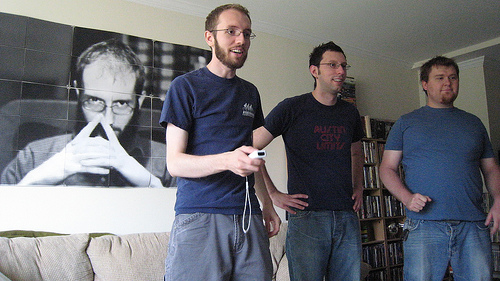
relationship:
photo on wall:
[2, 13, 217, 199] [1, 3, 430, 252]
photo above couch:
[2, 13, 217, 199] [0, 217, 297, 277]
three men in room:
[176, 3, 495, 265] [3, 3, 492, 276]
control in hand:
[238, 146, 268, 175] [235, 141, 260, 181]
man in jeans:
[158, 0, 285, 281] [392, 207, 488, 278]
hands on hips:
[274, 187, 368, 220] [272, 188, 362, 217]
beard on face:
[209, 39, 253, 69] [209, 6, 256, 65]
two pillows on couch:
[0, 232, 171, 279] [0, 229, 301, 279]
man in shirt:
[158, 0, 285, 281] [383, 103, 493, 226]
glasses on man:
[200, 22, 263, 44] [158, 0, 285, 281]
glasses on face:
[200, 22, 263, 44] [206, 3, 256, 68]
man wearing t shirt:
[158, 0, 285, 281] [159, 61, 270, 218]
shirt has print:
[167, 68, 274, 223] [239, 99, 260, 129]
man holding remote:
[158, 0, 285, 281] [248, 143, 264, 165]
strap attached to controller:
[238, 176, 257, 235] [247, 149, 268, 158]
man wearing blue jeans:
[158, 0, 285, 281] [164, 208, 279, 281]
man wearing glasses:
[158, 0, 285, 281] [204, 18, 257, 44]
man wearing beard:
[158, 0, 285, 281] [210, 31, 250, 72]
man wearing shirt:
[158, 0, 285, 281] [158, 64, 269, 218]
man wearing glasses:
[158, 0, 285, 281] [206, 22, 254, 41]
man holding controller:
[158, 0, 285, 281] [247, 149, 268, 158]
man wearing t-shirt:
[158, 0, 285, 281] [164, 66, 261, 218]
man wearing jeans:
[158, 0, 285, 281] [286, 202, 364, 276]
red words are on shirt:
[308, 122, 348, 157] [259, 86, 369, 213]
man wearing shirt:
[158, 0, 285, 281] [383, 103, 493, 226]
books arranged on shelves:
[359, 115, 408, 276] [348, 111, 405, 277]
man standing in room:
[374, 49, 498, 277] [3, 3, 492, 276]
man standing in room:
[246, 37, 381, 277] [3, 3, 492, 276]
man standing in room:
[158, 0, 271, 279] [3, 3, 492, 276]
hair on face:
[203, 4, 256, 26] [209, 6, 258, 70]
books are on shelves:
[359, 115, 408, 276] [351, 114, 410, 277]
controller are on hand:
[231, 147, 276, 236] [228, 141, 258, 184]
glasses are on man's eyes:
[200, 22, 263, 44] [217, 23, 253, 45]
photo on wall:
[2, 13, 217, 199] [14, 195, 157, 218]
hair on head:
[203, 4, 256, 26] [205, 7, 249, 69]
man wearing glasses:
[54, 36, 155, 162] [74, 89, 138, 118]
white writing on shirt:
[236, 95, 259, 123] [158, 64, 269, 218]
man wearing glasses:
[158, 0, 285, 281] [201, 24, 257, 38]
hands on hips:
[275, 188, 366, 213] [279, 192, 363, 221]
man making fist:
[158, 0, 285, 281] [400, 187, 432, 217]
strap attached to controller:
[231, 178, 266, 239] [239, 148, 270, 162]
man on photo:
[158, 0, 285, 281] [0, 12, 228, 189]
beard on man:
[212, 34, 247, 67] [158, 0, 285, 281]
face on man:
[214, 8, 251, 68] [158, 0, 285, 281]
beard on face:
[212, 34, 247, 67] [214, 8, 251, 68]